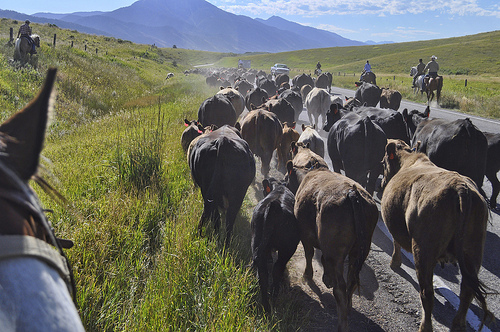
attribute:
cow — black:
[186, 123, 256, 249]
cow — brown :
[373, 131, 493, 329]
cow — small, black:
[246, 175, 302, 308]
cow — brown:
[369, 129, 483, 330]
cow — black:
[369, 126, 498, 326]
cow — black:
[404, 107, 479, 192]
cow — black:
[323, 102, 388, 194]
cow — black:
[248, 174, 302, 321]